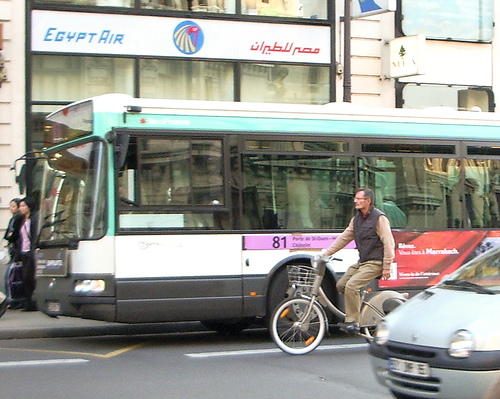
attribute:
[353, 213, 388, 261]
jacket — brown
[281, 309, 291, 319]
reflector — orange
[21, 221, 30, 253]
shirt — pink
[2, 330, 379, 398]
street — black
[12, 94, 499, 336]
bus — white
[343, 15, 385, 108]
wall — white